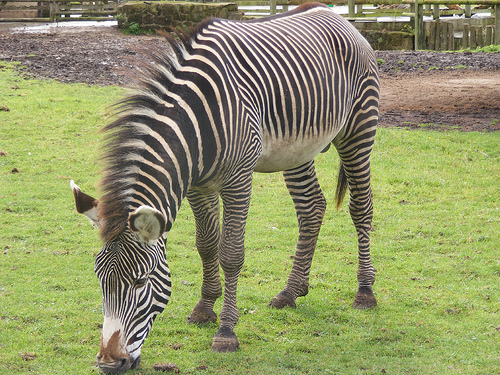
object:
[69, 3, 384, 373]
zebra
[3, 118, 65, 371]
grass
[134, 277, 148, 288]
eye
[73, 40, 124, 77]
dirt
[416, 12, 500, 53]
fence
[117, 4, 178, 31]
bushes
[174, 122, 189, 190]
stripes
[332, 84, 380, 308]
legs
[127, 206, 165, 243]
ears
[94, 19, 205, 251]
mane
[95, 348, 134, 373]
nose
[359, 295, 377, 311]
hooves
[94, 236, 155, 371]
face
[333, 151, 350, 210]
tail